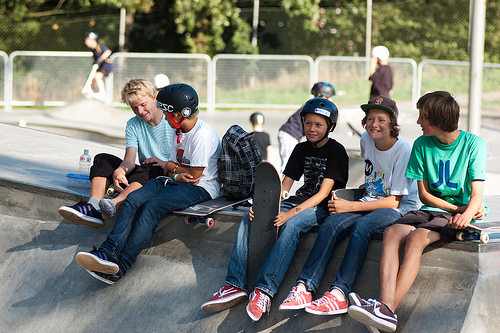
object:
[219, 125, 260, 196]
book bag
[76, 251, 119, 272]
tinnis shoe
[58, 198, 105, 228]
tinnis shoe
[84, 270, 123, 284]
tinnis shoe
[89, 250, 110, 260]
stripe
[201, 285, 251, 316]
tinnis shoe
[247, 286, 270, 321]
tinnis shoe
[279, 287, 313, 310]
tinnis shoe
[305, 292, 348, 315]
tinnis shoe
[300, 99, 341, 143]
helmet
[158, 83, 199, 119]
helmet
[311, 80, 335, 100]
helmet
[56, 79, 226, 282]
boy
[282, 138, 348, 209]
shirt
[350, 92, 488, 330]
boy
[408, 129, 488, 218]
shirt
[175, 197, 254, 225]
skateboard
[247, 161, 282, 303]
skateboard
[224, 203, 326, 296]
jeans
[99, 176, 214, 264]
jeans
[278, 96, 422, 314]
boy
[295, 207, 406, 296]
jeans